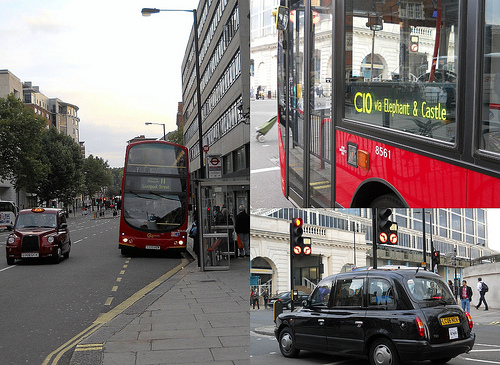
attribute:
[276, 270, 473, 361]
car — black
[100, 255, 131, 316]
lines — yellow, dotted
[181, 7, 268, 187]
building — tall, beige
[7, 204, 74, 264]
taxi — red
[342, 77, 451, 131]
sign — painted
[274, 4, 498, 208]
bus — double decker, large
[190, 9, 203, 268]
pole — tall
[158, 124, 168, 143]
pole — tall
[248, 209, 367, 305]
building — large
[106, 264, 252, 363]
pattern — decorative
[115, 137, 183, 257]
bus — stopped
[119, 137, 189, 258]
bus — red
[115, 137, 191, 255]
bus — double decker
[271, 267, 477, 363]
cab — black, taxi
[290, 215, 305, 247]
traffic light — red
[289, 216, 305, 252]
caution light — yellow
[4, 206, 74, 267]
cab — taxi